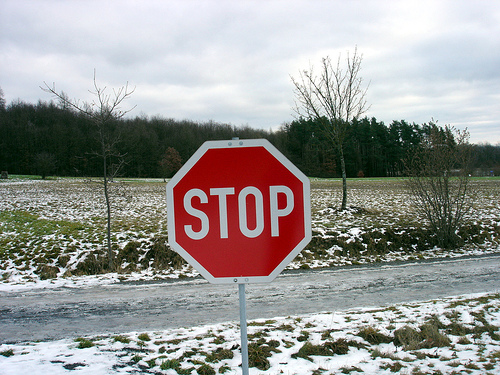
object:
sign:
[181, 145, 304, 296]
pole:
[223, 296, 262, 343]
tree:
[331, 94, 363, 141]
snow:
[358, 299, 393, 321]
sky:
[160, 18, 230, 59]